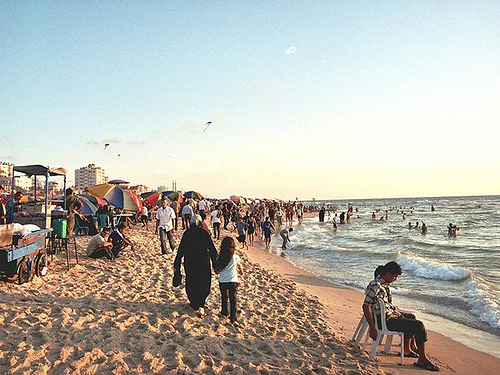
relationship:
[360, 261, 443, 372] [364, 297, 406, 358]
people sitting chair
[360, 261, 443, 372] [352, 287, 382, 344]
people sitting chair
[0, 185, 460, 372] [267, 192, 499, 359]
people gathering at water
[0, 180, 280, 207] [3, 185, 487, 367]
umbrellas lining beach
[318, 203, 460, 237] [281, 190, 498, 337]
people swimming in water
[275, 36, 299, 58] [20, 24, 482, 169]
cloud in sky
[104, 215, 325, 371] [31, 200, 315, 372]
footprints are in sand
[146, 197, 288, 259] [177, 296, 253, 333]
people walking in sand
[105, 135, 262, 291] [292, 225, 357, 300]
people in coastal area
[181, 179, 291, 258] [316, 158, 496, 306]
people close to ocean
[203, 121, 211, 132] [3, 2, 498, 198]
kite in sky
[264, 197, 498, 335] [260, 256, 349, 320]
tide coming shore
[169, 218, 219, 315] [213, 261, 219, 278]
woman holding girl's hand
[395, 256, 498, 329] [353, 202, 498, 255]
wave in water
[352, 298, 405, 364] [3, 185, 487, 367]
chair on beach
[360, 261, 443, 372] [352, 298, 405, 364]
people on chair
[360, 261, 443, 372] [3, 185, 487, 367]
people on beach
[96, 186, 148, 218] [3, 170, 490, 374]
umbrella on beach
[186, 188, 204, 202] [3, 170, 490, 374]
umbrella on beach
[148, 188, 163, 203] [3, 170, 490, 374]
umbrella on beach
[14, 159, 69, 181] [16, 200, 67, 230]
canopy on top stand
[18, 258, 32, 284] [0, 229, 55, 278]
wheel on cart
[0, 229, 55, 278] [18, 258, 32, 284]
cart has wheel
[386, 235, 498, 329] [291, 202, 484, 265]
wave in water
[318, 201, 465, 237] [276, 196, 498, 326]
people in water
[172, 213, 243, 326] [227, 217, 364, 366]
people on beach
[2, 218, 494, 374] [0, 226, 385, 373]
sand has tracks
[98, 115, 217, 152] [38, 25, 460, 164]
kites in sky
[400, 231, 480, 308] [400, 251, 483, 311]
water has waves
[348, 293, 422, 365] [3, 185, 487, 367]
chair on beach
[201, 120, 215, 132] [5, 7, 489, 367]
kite in air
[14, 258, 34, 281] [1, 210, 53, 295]
wheel of cart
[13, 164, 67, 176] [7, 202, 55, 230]
canopy over stand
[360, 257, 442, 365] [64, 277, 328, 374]
people on beach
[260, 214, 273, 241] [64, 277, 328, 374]
people on beach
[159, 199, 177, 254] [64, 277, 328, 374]
people on beach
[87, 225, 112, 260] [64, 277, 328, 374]
people on beach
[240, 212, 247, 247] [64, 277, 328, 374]
people on beach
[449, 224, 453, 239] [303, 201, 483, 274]
person in water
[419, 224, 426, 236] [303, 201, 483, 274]
person in water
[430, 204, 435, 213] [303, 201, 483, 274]
person in water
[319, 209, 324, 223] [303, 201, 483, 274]
person in water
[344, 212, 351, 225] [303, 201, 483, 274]
person in water